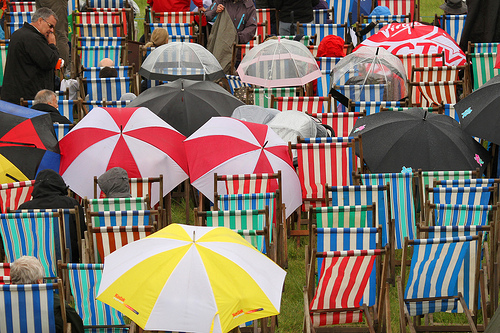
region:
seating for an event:
[18, 7, 450, 317]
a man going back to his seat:
[0, 10, 85, 106]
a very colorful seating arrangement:
[31, 6, 447, 280]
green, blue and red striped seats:
[315, 173, 492, 325]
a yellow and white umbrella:
[76, 224, 296, 332]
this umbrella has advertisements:
[359, 13, 466, 75]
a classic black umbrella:
[346, 91, 495, 188]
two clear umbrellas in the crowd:
[119, 23, 339, 86]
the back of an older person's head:
[1, 248, 55, 286]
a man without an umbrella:
[20, 92, 85, 139]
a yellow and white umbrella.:
[90, 212, 290, 331]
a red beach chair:
[285, 244, 380, 331]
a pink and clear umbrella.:
[228, 23, 330, 91]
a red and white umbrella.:
[52, 84, 187, 215]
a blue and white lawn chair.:
[379, 220, 486, 332]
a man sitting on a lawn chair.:
[3, 0, 75, 114]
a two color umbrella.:
[55, 97, 188, 208]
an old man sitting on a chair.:
[0, 254, 55, 289]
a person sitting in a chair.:
[297, 20, 363, 78]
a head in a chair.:
[91, 51, 117, 85]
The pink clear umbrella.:
[238, 33, 311, 83]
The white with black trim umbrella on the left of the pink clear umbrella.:
[130, 40, 210, 76]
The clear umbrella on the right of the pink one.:
[337, 36, 408, 103]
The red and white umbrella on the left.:
[60, 99, 183, 194]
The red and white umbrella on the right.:
[188, 124, 308, 205]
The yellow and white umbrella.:
[91, 235, 299, 332]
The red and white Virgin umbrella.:
[357, 18, 472, 79]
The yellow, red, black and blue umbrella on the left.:
[5, 94, 47, 179]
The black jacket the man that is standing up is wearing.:
[12, 13, 57, 93]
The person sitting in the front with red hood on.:
[318, 26, 355, 61]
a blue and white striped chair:
[384, 223, 498, 332]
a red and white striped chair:
[290, 240, 427, 330]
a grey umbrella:
[126, 53, 248, 156]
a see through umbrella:
[326, 38, 429, 124]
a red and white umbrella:
[174, 104, 301, 217]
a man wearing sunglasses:
[3, 5, 74, 90]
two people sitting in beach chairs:
[28, 155, 157, 237]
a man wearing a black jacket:
[14, 1, 71, 89]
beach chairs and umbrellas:
[124, 80, 449, 296]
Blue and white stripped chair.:
[396, 231, 481, 323]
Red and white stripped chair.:
[305, 250, 386, 329]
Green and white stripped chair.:
[202, 208, 266, 235]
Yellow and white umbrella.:
[91, 223, 286, 330]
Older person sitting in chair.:
[2, 251, 74, 330]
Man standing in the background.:
[6, 7, 65, 105]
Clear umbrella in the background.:
[321, 41, 413, 106]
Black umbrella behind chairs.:
[464, 104, 487, 177]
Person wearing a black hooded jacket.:
[10, 168, 84, 237]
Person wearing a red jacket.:
[145, 0, 210, 17]